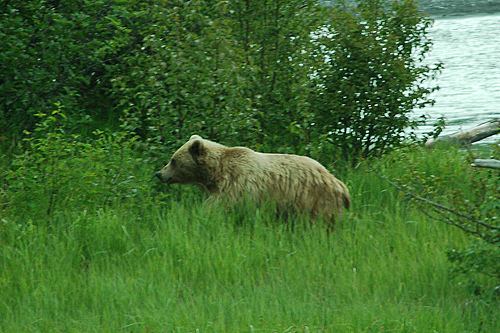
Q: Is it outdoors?
A: Yes, it is outdoors.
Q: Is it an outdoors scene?
A: Yes, it is outdoors.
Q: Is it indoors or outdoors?
A: It is outdoors.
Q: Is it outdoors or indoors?
A: It is outdoors.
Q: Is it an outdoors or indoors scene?
A: It is outdoors.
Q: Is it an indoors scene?
A: No, it is outdoors.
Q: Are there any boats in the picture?
A: No, there are no boats.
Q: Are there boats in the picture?
A: No, there are no boats.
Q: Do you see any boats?
A: No, there are no boats.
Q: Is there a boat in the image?
A: No, there are no boats.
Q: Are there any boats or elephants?
A: No, there are no boats or elephants.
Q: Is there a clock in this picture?
A: No, there are no clocks.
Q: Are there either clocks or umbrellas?
A: No, there are no clocks or umbrellas.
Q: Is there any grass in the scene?
A: Yes, there is grass.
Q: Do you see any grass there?
A: Yes, there is grass.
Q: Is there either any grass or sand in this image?
A: Yes, there is grass.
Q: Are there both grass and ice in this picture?
A: No, there is grass but no ice.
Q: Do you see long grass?
A: Yes, there is long grass.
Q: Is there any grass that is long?
A: Yes, there is grass that is long.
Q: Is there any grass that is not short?
A: Yes, there is long grass.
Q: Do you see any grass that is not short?
A: Yes, there is long grass.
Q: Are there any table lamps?
A: No, there are no table lamps.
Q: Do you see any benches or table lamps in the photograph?
A: No, there are no table lamps or benches.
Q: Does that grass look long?
A: Yes, the grass is long.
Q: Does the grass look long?
A: Yes, the grass is long.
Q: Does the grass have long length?
A: Yes, the grass is long.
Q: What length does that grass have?
A: The grass has long length.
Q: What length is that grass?
A: The grass is long.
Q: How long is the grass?
A: The grass is long.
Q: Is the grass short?
A: No, the grass is long.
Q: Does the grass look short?
A: No, the grass is long.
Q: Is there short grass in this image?
A: No, there is grass but it is long.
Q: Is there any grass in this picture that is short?
A: No, there is grass but it is long.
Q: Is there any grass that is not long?
A: No, there is grass but it is long.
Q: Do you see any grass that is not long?
A: No, there is grass but it is long.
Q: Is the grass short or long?
A: The grass is long.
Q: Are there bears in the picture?
A: Yes, there is a bear.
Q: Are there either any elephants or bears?
A: Yes, there is a bear.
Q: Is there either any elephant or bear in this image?
A: Yes, there is a bear.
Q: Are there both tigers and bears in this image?
A: No, there is a bear but no tigers.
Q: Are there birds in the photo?
A: No, there are no birds.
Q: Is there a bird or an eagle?
A: No, there are no birds or eagles.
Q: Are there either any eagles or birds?
A: No, there are no birds or eagles.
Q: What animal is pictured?
A: The animal is a bear.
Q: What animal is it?
A: The animal is a bear.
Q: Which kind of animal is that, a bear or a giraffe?
A: That is a bear.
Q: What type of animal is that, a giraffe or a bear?
A: That is a bear.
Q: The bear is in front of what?
A: The bear is in front of the shrubs.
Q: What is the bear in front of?
A: The bear is in front of the shrubs.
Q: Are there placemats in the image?
A: No, there are no placemats.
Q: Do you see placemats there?
A: No, there are no placemats.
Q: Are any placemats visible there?
A: No, there are no placemats.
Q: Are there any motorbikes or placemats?
A: No, there are no placemats or motorbikes.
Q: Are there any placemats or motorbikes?
A: No, there are no placemats or motorbikes.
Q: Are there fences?
A: No, there are no fences.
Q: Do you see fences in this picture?
A: No, there are no fences.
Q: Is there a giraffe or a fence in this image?
A: No, there are no fences or giraffes.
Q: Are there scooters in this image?
A: No, there are no scooters.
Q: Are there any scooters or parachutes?
A: No, there are no scooters or parachutes.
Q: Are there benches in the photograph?
A: No, there are no benches.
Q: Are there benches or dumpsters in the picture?
A: No, there are no benches or dumpsters.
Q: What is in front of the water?
A: The shrubs are in front of the water.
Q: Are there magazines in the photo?
A: No, there are no magazines.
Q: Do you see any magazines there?
A: No, there are no magazines.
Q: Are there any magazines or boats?
A: No, there are no magazines or boats.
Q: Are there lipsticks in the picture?
A: No, there are no lipsticks.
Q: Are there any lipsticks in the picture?
A: No, there are no lipsticks.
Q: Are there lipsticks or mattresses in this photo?
A: No, there are no lipsticks or mattresses.